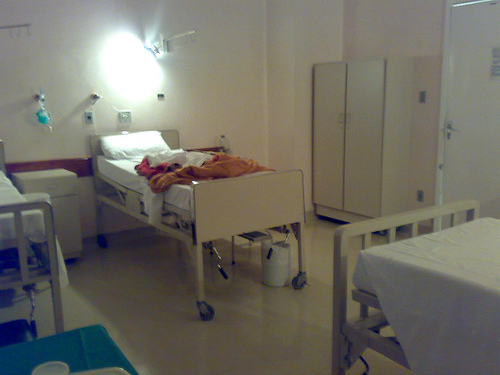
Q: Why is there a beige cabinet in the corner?
A: To hold patients belongings.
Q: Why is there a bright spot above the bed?
A: The light is on.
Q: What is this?
A: A slept in hospital bed.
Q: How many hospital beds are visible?
A: Three.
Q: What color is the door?
A: White.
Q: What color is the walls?
A: White.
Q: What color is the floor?
A: White.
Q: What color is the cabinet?
A: White.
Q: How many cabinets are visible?
A: One.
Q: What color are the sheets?
A: White.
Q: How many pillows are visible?
A: One.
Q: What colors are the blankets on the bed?
A: Red and Orange.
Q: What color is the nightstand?
A: White.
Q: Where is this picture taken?
A: Hospital.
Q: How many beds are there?
A: 3.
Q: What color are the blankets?
A: Red and orange.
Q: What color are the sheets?
A: White.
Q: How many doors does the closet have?
A: 2.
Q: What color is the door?
A: White.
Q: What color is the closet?
A: Cream.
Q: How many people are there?
A: 0.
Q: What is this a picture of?
A: Hospital room.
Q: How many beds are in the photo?
A: 3.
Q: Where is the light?
A: Above the bed.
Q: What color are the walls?
A: White.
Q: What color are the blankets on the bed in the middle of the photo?
A: Brown and red.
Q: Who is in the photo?
A: No one.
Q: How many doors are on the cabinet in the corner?
A: 2.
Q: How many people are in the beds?
A: None.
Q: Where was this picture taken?
A: At a hospital.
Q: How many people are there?
A: None.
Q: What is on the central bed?
A: Blankets.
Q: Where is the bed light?
A: Above the bed.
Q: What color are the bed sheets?
A: White.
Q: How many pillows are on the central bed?
A: 1.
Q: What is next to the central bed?
A: A cabinet.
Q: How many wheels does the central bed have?
A: 4.